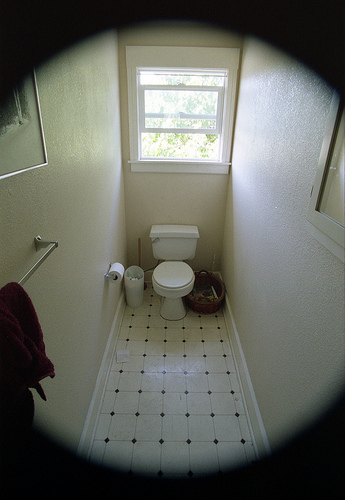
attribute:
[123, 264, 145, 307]
garbage can — white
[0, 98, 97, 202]
picture — silver, framed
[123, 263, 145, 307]
trash can — white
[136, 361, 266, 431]
tiles — floor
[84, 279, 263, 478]
floor — white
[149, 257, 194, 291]
lid — toilet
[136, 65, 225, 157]
window — open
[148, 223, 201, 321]
toilet — silver 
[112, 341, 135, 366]
tissue — piece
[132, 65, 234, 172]
window — open up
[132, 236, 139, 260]
handle — wooden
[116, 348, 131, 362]
toilet paper — white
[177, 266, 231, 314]
basket — wicker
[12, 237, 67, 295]
towel rack — silver 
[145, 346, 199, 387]
diamonds — black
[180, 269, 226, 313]
basket — Brown 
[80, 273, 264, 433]
base board — white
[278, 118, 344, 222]
cabinet — medicine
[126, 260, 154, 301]
can — white, plastic, garbage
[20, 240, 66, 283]
rack — silver, metal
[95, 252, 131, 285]
tissue — roll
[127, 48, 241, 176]
trimming — white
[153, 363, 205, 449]
design — diamond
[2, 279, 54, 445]
towel — fluffy, dark red